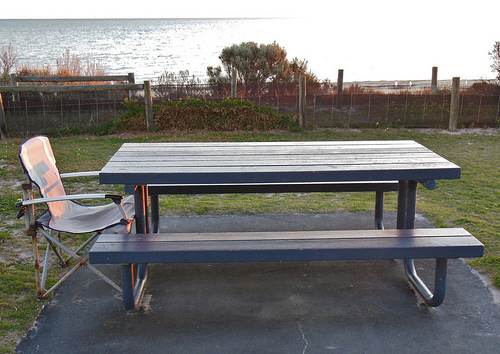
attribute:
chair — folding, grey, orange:
[10, 132, 141, 306]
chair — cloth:
[15, 129, 150, 302]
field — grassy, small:
[0, 129, 499, 352]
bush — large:
[206, 44, 316, 92]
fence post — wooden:
[295, 69, 310, 127]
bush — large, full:
[218, 39, 293, 95]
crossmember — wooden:
[6, 69, 136, 84]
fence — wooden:
[0, 98, 138, 128]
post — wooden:
[140, 81, 156, 131]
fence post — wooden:
[141, 77, 156, 132]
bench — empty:
[84, 225, 485, 307]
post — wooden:
[426, 57, 448, 92]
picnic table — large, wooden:
[87, 142, 486, 314]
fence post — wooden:
[441, 70, 465, 137]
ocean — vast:
[47, 39, 377, 84]